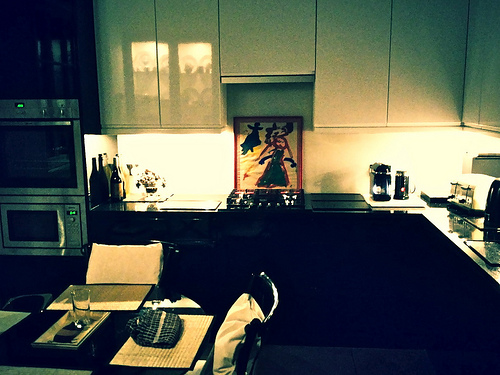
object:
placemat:
[44, 283, 154, 312]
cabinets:
[463, 0, 500, 133]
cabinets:
[215, 0, 313, 79]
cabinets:
[386, 0, 467, 125]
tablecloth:
[107, 307, 214, 367]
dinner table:
[0, 286, 219, 374]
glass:
[72, 292, 89, 303]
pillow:
[211, 292, 264, 374]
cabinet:
[92, 0, 162, 130]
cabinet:
[154, 0, 221, 128]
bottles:
[115, 154, 126, 199]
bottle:
[110, 158, 123, 202]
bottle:
[89, 157, 103, 202]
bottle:
[98, 154, 109, 200]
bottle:
[102, 153, 112, 198]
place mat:
[108, 313, 215, 371]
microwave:
[7, 209, 60, 242]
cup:
[70, 288, 92, 329]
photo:
[233, 116, 304, 194]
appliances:
[0, 99, 89, 259]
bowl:
[30, 310, 111, 349]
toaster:
[232, 122, 309, 194]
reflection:
[111, 30, 223, 130]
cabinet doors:
[312, 0, 390, 127]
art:
[240, 122, 298, 188]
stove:
[222, 187, 300, 208]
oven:
[0, 99, 86, 196]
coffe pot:
[369, 162, 391, 200]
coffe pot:
[393, 171, 409, 200]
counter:
[421, 208, 499, 286]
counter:
[106, 186, 473, 218]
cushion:
[86, 243, 165, 286]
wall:
[121, 88, 464, 206]